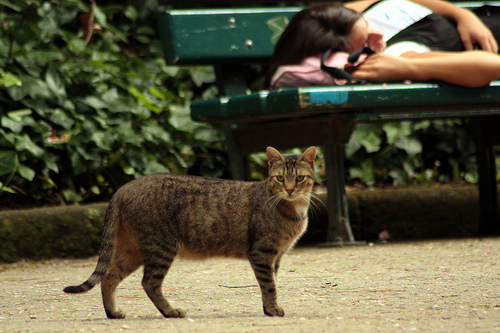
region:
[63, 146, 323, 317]
cat standing in the park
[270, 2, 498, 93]
woman sleeping on bench in the park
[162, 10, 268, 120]
edge of green bench in the park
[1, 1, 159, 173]
green foliage behind the bench in the park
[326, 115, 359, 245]
metal leg holding up the bench in the park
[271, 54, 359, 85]
pink bag being used as pillow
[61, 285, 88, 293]
tip of cats tail in the park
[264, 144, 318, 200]
cats head standing in the park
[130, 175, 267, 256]
body of cat standing in the park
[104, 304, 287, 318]
cat paws on the ground in the park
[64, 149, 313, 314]
a cat standing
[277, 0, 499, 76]
a person laying on the bench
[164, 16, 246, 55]
the bench is green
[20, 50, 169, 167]
the leaves are green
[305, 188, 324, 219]
whiskers on the cat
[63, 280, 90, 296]
the cats tail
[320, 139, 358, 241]
the legs on the bench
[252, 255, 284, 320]
the cats front legs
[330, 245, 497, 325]
the ground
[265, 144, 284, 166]
the cats ear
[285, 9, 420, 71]
woman lying on a bench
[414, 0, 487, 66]
woman has arm across her chest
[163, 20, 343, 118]
bench is green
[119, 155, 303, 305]
cat standing on the ground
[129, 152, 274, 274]
cat is black and brown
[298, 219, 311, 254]
cat has white on his chest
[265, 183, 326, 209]
cat's whiskers are white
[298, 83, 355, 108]
paint missing from the bench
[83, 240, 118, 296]
cat has stripes on it's tail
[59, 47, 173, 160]
shrubs behind the cat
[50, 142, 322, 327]
the cat on the ground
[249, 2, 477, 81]
the woman on the bench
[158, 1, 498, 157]
the bench is green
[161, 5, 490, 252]
the bench is wooden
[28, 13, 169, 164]
the bush behind the bench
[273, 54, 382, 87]
the pink bag on the bench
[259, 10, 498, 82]
the woman lying down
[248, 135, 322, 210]
the head of the cat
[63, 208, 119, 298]
the tail of the cat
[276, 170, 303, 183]
the eyes of the cat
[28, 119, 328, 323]
cat is gray and black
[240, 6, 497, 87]
woman laying on bench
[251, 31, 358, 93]
woman laying on jacket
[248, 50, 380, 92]
the jacket is pink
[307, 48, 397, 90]
woman is holding sunglasses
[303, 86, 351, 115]
paint coming off bench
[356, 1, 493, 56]
woman wearing black and white clothes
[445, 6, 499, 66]
woman laying hand on stomach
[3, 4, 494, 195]
plants behind the woman